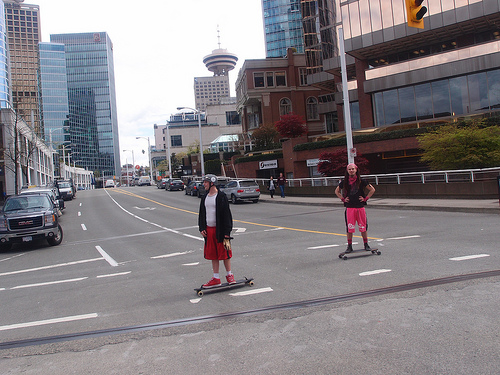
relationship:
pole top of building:
[216, 24, 223, 46] [199, 46, 240, 78]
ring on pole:
[196, 54, 239, 61] [216, 24, 223, 46]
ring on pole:
[204, 61, 237, 68] [216, 24, 223, 46]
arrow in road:
[129, 202, 156, 214] [2, 182, 499, 371]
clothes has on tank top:
[198, 190, 233, 260] [202, 192, 219, 226]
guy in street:
[197, 174, 236, 289] [2, 163, 494, 373]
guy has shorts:
[334, 162, 379, 253] [336, 203, 374, 237]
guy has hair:
[334, 162, 379, 253] [339, 170, 362, 200]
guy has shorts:
[196, 175, 234, 287] [203, 227, 230, 259]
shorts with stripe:
[203, 227, 230, 259] [222, 252, 230, 262]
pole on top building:
[217, 24, 221, 48] [49, 31, 121, 187]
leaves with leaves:
[275, 111, 309, 137] [285, 117, 299, 136]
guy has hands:
[334, 162, 379, 253] [341, 194, 365, 204]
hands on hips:
[341, 194, 365, 204] [345, 198, 368, 208]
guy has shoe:
[197, 174, 236, 289] [227, 272, 234, 281]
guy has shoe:
[197, 174, 236, 289] [199, 278, 220, 288]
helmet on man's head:
[203, 172, 222, 187] [197, 169, 226, 195]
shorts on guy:
[326, 199, 408, 252] [334, 162, 375, 253]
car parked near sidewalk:
[0, 192, 63, 245] [2, 191, 111, 372]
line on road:
[90, 240, 123, 277] [2, 182, 499, 371]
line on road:
[77, 217, 92, 234] [2, 182, 499, 371]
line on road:
[75, 204, 85, 219] [2, 182, 499, 371]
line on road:
[77, 200, 83, 208] [2, 182, 499, 371]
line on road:
[103, 181, 208, 256] [2, 182, 499, 371]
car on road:
[0, 188, 67, 251] [2, 182, 499, 371]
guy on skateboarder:
[334, 162, 375, 253] [194, 275, 256, 296]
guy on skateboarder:
[197, 174, 236, 289] [194, 275, 256, 296]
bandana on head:
[344, 162, 354, 167] [345, 162, 358, 178]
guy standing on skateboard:
[334, 162, 375, 253] [338, 246, 381, 263]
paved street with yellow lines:
[75, 186, 300, 313] [257, 208, 331, 243]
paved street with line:
[75, 186, 300, 313] [103, 187, 205, 242]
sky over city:
[31, 2, 281, 169] [0, 0, 495, 247]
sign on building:
[253, 157, 280, 170] [231, 47, 315, 192]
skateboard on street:
[333, 245, 382, 263] [269, 221, 438, 298]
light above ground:
[402, 15, 431, 30] [0, 187, 500, 375]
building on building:
[299, 0, 500, 173] [143, 9, 489, 172]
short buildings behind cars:
[1, 93, 98, 212] [1, 173, 78, 261]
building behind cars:
[49, 31, 121, 187] [1, 173, 78, 261]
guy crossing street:
[197, 174, 236, 289] [38, 161, 470, 371]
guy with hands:
[334, 162, 375, 253] [336, 191, 369, 203]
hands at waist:
[336, 191, 369, 203] [335, 203, 378, 211]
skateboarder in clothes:
[120, 145, 281, 337] [194, 185, 242, 271]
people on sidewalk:
[248, 162, 305, 209] [248, 181, 498, 223]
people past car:
[248, 162, 305, 209] [219, 170, 264, 208]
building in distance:
[52, 32, 129, 174] [0, 2, 338, 194]